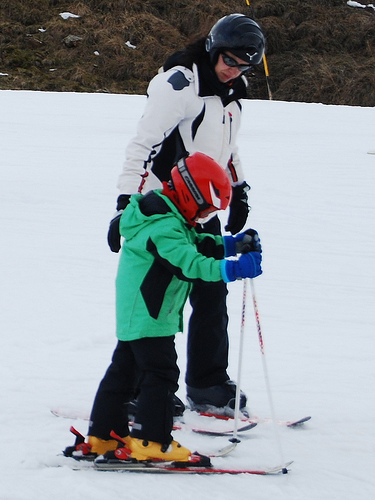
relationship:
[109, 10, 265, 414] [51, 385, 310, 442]
woman wearing skis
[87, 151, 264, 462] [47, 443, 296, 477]
child wearing skis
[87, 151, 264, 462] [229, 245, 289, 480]
child holding ski poles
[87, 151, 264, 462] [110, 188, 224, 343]
child wearing coat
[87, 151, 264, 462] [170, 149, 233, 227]
child wearing helmet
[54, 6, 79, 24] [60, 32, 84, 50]
snow on a rock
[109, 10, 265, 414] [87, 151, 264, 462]
woman helping child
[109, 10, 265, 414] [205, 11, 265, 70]
woman wearing helmet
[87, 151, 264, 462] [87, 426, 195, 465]
child wearing boots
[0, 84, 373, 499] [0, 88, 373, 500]
ground covered with snow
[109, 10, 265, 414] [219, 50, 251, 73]
woman wearing sunglasses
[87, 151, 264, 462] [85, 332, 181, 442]
child wearing ski pants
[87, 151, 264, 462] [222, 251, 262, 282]
child wearing right glove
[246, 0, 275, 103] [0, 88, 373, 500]
pole in snow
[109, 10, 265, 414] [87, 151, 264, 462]
woman looking at child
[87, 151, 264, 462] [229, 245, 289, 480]
child using ski poles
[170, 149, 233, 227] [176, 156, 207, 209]
helmet has stripes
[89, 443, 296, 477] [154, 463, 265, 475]
skis has stripe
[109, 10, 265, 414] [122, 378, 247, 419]
woman wearing snow shoes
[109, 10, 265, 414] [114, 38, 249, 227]
woman wearing coat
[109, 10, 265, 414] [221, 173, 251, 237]
woman wearing left glove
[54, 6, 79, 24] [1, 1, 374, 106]
snow on ground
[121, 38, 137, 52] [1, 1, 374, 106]
snow on ground